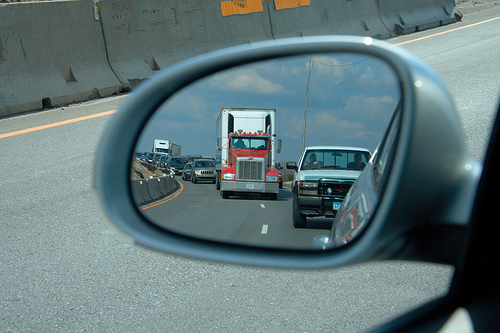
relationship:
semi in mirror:
[211, 105, 291, 198] [76, 24, 464, 275]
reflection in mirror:
[143, 54, 406, 255] [76, 24, 464, 275]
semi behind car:
[211, 105, 291, 198] [287, 136, 379, 231]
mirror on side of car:
[76, 24, 464, 275] [430, 27, 498, 332]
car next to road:
[287, 136, 379, 231] [156, 163, 359, 249]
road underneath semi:
[156, 163, 359, 249] [211, 105, 291, 198]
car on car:
[290, 144, 373, 227] [287, 136, 379, 231]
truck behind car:
[150, 135, 186, 155] [151, 153, 167, 167]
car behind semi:
[193, 156, 220, 186] [211, 105, 291, 198]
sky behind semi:
[157, 52, 399, 144] [211, 105, 291, 198]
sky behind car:
[157, 52, 399, 144] [287, 136, 379, 231]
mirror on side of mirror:
[76, 24, 464, 275] [93, 34, 467, 270]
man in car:
[301, 149, 331, 172] [287, 136, 379, 231]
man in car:
[342, 147, 373, 175] [287, 136, 379, 231]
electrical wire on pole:
[314, 54, 380, 71] [294, 52, 318, 155]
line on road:
[252, 196, 271, 213] [156, 163, 359, 249]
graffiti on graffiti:
[110, 8, 190, 37] [110, 8, 190, 37]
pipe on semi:
[235, 124, 265, 137] [211, 105, 291, 198]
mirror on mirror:
[76, 24, 464, 275] [93, 34, 467, 270]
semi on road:
[211, 105, 291, 198] [156, 163, 359, 249]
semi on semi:
[211, 105, 291, 198] [211, 105, 291, 198]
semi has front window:
[211, 105, 291, 198] [211, 132, 228, 154]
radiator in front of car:
[323, 193, 349, 217] [287, 136, 379, 231]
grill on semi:
[234, 158, 270, 185] [211, 105, 291, 198]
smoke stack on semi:
[221, 114, 272, 141] [211, 105, 291, 198]